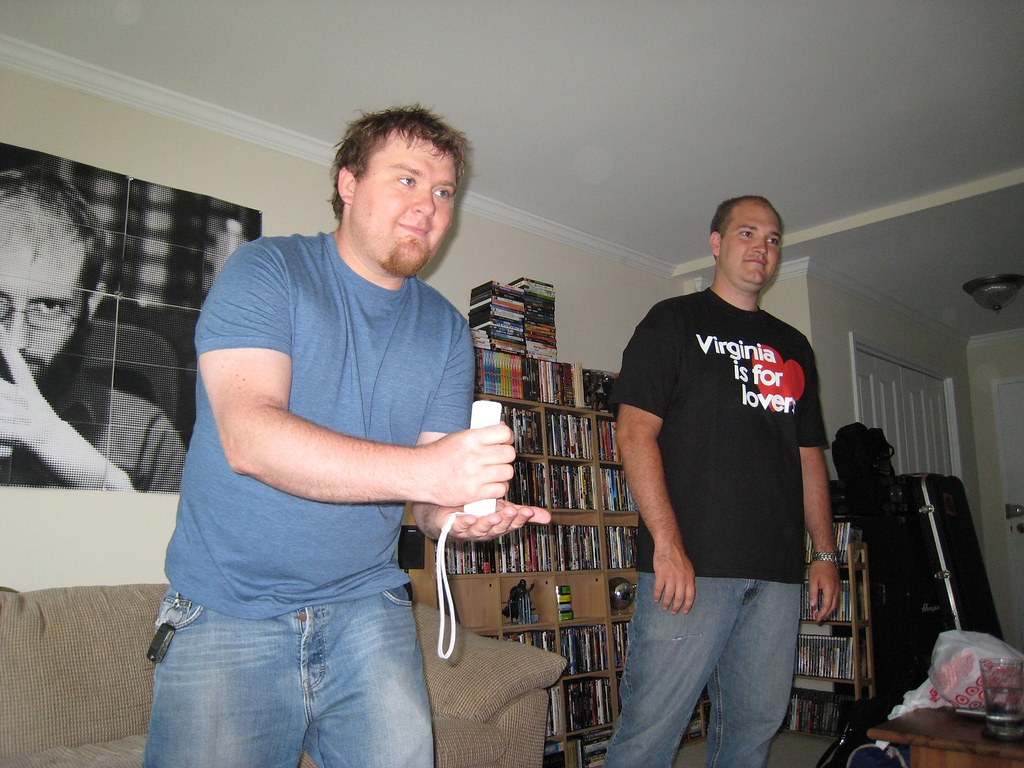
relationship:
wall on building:
[17, 113, 789, 701] [34, 11, 961, 722]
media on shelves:
[547, 410, 589, 458] [537, 412, 585, 462]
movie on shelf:
[601, 416, 615, 468] [580, 405, 620, 462]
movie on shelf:
[567, 367, 583, 417] [521, 401, 615, 460]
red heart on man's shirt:
[759, 356, 807, 409] [612, 289, 829, 581]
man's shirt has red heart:
[612, 289, 829, 581] [759, 356, 807, 409]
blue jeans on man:
[147, 587, 441, 765] [140, 102, 548, 767]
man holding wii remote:
[140, 102, 548, 767] [459, 399, 511, 525]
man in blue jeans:
[140, 102, 548, 767] [147, 587, 441, 765]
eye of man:
[394, 163, 427, 192] [140, 102, 548, 767]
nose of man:
[412, 197, 439, 215] [140, 102, 548, 767]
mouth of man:
[386, 215, 445, 244] [140, 102, 548, 767]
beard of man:
[377, 235, 432, 278] [140, 102, 548, 767]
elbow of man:
[211, 431, 276, 486] [140, 102, 548, 767]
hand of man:
[405, 420, 520, 511] [140, 102, 548, 767]